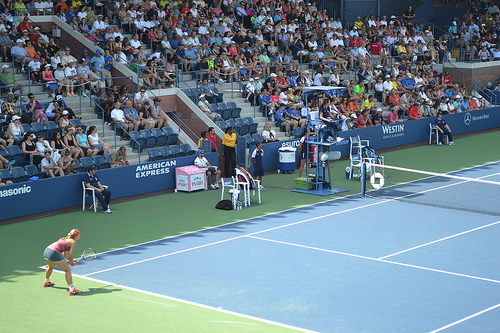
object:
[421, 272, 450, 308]
part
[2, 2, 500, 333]
tennis game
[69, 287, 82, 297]
pink shoes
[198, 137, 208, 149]
yellow shirt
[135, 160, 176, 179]
american express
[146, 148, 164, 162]
empty chairs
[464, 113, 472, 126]
mercedes logo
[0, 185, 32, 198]
panasonic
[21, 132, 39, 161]
woman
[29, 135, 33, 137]
glasses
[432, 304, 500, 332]
white lines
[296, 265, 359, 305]
part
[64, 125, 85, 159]
girl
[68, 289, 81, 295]
right foot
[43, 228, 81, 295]
girl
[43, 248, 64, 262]
blue skirt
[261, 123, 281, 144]
people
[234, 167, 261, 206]
chairs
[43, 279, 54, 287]
shoes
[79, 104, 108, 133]
stairs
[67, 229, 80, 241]
her head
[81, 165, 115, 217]
score keep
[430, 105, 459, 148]
score keep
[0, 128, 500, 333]
court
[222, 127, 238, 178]
person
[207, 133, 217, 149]
shirt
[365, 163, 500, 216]
net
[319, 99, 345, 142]
linesman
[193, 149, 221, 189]
person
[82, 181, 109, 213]
chair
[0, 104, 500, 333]
trim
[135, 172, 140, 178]
writing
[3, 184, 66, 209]
wall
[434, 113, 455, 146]
man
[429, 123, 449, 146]
chair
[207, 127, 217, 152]
person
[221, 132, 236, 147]
shirt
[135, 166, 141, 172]
text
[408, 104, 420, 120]
man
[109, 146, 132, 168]
people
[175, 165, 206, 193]
box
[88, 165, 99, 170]
hat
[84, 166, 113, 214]
man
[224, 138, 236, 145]
yellow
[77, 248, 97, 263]
racket